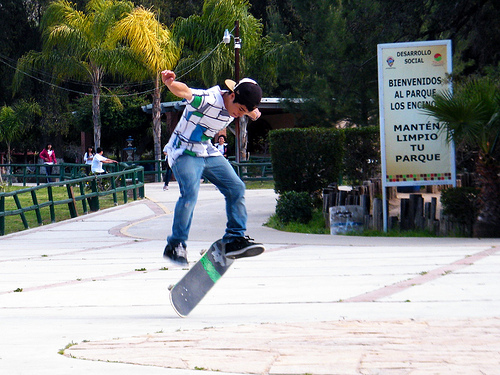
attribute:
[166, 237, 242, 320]
board — black, green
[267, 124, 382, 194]
hedge — green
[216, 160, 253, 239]
leg — apart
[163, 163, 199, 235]
leg — apart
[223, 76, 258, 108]
baseball cap — black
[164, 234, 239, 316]
skateboard — black 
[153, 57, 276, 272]
boy — skating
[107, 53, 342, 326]
shirt — white, patterned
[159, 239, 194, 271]
shoes — black, white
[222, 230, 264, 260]
shoes — white, black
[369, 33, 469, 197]
sign — spanish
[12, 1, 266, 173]
trees — green, yellow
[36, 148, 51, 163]
shirt — red 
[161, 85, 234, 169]
shirt — white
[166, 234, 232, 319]
board — black 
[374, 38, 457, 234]
sign — tall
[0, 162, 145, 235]
fence — green 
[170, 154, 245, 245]
pants — blue